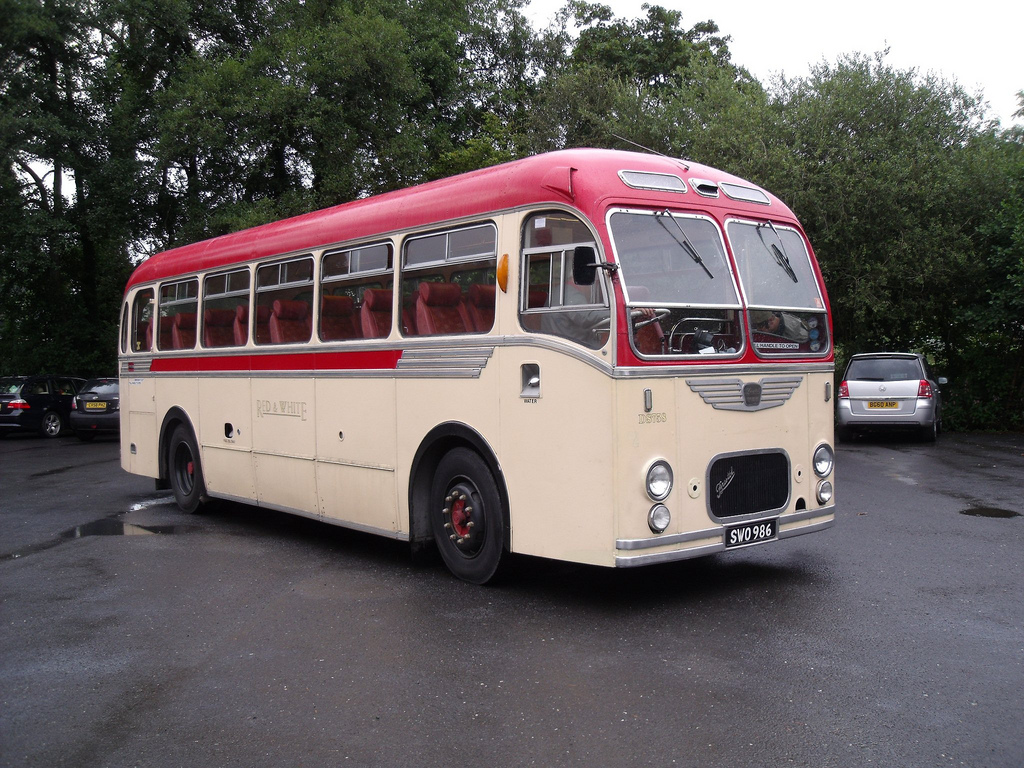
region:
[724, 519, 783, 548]
black sign with white letters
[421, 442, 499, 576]
front black tire on bus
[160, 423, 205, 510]
back black tire on bus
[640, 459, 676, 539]
front head lights on bus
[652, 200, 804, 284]
long black windshield wipers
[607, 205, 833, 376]
wide double front windows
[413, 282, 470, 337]
dark red chair in bus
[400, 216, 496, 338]
large square window on bus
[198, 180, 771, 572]
red and white bus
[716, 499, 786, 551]
white license on bus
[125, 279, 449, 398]
red stripe on bus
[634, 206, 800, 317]
black wipers on window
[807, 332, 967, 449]
grey car is parked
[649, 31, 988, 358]
green and leafy trees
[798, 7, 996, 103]
grey and white sky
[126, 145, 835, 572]
the bus is retro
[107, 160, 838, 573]
the bus is red and white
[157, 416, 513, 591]
the wheels are black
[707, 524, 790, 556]
the license plate is white and black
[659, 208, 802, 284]
the windsheild wipers are small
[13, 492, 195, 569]
the floor has a puddle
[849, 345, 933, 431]
the car is gray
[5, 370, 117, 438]
the cars are parked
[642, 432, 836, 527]
the bus has headlights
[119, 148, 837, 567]
the bus is outdoors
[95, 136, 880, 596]
Bus in a lot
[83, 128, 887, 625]
Bus is in a lot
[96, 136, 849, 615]
Bus is parked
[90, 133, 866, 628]
Bus is parked in a lot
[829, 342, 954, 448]
Car is parked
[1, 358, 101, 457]
Black car is parked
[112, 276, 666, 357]
Seats on the bus are red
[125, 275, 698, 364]
Red seats are on the bus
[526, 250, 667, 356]
Person in front of the steering wheel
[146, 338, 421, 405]
red stripe on bus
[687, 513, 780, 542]
black and white license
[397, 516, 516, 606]
black tire on bus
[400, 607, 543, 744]
lot is dark grey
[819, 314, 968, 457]
grey van is parked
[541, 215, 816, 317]
wipers on front windows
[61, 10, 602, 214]
green and tall trees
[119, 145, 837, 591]
Red and off white bus.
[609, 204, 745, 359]
Larger front windshield of a bus.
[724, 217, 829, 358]
Front windshield on a bus near a silver van.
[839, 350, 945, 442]
A silver parked van.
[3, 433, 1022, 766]
A black paved road.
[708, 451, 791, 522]
A black bus grill.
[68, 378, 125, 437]
A parked dark grey car.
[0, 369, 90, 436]
A long black van parked.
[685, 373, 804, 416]
Silver wings on a bus front.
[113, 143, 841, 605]
large white and red bus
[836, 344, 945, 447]
silver car parked behind bus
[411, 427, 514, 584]
large round black tire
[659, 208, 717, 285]
windshield wiper on front window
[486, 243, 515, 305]
orange light on side of bus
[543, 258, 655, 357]
man sitting in driver's seat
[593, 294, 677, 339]
large round metal steering wheel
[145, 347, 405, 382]
red stripe on side of bus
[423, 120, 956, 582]
front of the bus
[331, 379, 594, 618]
front tire of bus